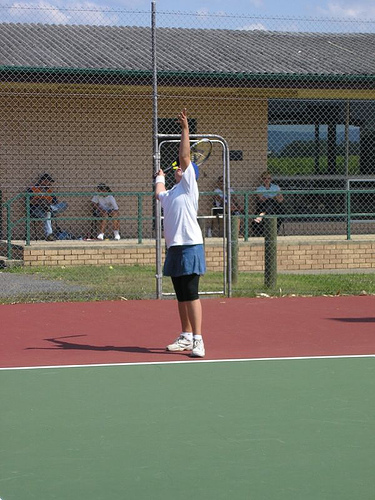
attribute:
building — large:
[5, 23, 373, 268]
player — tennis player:
[155, 107, 206, 357]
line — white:
[0, 352, 374, 370]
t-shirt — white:
[158, 161, 203, 246]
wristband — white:
[151, 172, 178, 187]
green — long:
[296, 190, 336, 195]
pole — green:
[297, 189, 373, 194]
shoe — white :
[191, 337, 205, 357]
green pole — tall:
[264, 216, 279, 296]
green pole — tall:
[225, 215, 243, 284]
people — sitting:
[18, 170, 123, 244]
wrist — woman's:
[151, 175, 169, 183]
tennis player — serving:
[154, 106, 205, 356]